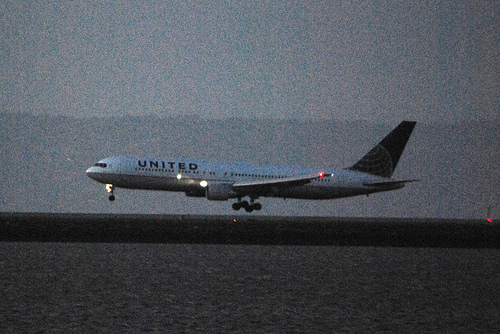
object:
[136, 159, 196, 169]
united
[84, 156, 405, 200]
body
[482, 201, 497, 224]
tower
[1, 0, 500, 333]
picture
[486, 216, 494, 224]
light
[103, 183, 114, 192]
landing gear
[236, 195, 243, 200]
landing gear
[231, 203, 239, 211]
wheel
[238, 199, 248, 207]
wheel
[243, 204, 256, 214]
wheel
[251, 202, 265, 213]
wheel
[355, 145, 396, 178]
logo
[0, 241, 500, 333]
water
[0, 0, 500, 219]
sky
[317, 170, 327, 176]
red light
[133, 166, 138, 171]
windows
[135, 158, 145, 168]
letters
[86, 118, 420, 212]
plane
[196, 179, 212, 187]
light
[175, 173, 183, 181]
light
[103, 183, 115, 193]
light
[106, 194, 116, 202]
gear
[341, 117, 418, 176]
part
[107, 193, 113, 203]
wheels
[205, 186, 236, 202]
engine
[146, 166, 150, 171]
windows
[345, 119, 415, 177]
tail wing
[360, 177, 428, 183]
wings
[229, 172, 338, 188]
wings